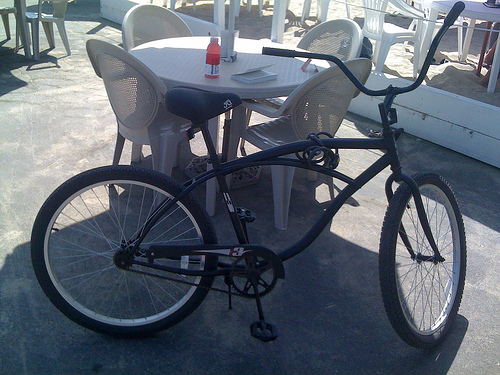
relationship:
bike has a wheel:
[31, 1, 467, 352] [30, 164, 218, 338]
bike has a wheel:
[31, 1, 467, 352] [378, 170, 466, 350]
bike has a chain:
[31, 1, 467, 352] [114, 248, 280, 298]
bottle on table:
[204, 37, 220, 79] [126, 36, 337, 191]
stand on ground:
[186, 101, 264, 192] [1, 1, 500, 375]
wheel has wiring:
[30, 164, 218, 338] [47, 183, 201, 320]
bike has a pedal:
[31, 1, 467, 352] [250, 321, 279, 343]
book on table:
[232, 64, 278, 85] [126, 36, 337, 191]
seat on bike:
[166, 85, 242, 125] [31, 1, 467, 352]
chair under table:
[121, 2, 195, 51] [126, 36, 337, 191]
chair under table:
[255, 19, 363, 114] [126, 36, 337, 191]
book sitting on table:
[232, 64, 278, 85] [126, 36, 337, 191]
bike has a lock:
[31, 1, 467, 352] [296, 131, 339, 171]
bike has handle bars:
[31, 1, 467, 352] [261, 2, 466, 97]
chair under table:
[225, 58, 373, 228] [126, 36, 337, 191]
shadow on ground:
[0, 150, 468, 375] [1, 1, 500, 375]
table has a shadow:
[126, 36, 337, 191] [0, 150, 468, 375]